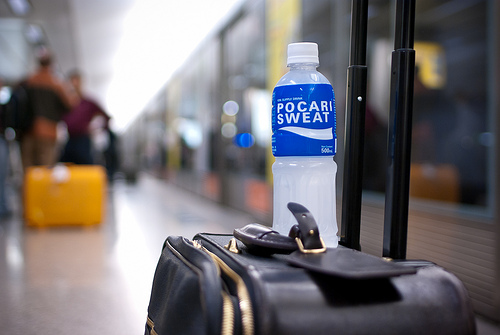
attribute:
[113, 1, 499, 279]
train — here, steel, silver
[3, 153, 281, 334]
platform — white, shiny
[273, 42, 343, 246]
water bottle — here, plastic, blue, white, clear, full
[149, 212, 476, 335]
suitcase — here, leather, black, yellow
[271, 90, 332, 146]
label — blue, white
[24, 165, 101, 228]
suitcase — yellow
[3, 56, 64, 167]
man — balding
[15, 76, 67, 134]
jacket — orange, black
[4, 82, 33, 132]
backpack — black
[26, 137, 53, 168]
pants — khaki, black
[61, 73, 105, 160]
person — standing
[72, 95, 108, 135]
shirt — maroon, purple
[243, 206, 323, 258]
handle — up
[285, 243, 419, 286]
tag — black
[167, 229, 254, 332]
zippers — golden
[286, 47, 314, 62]
bottle cap — white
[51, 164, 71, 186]
luggage tag — white